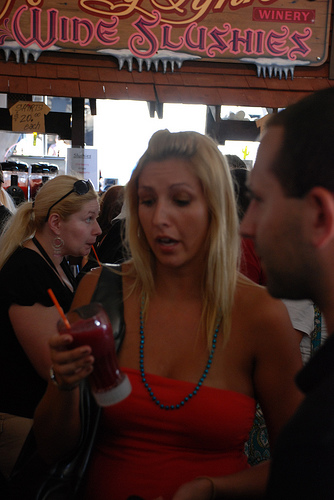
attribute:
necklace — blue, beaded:
[130, 261, 225, 411]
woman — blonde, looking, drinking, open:
[42, 127, 314, 477]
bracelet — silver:
[207, 476, 220, 497]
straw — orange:
[45, 289, 73, 327]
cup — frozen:
[57, 298, 134, 411]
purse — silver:
[41, 267, 131, 500]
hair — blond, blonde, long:
[118, 118, 244, 344]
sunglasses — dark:
[43, 179, 96, 221]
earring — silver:
[48, 235, 67, 256]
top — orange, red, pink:
[77, 370, 266, 499]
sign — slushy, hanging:
[2, 0, 329, 70]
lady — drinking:
[0, 166, 103, 457]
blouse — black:
[4, 249, 79, 424]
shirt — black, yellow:
[263, 338, 332, 499]